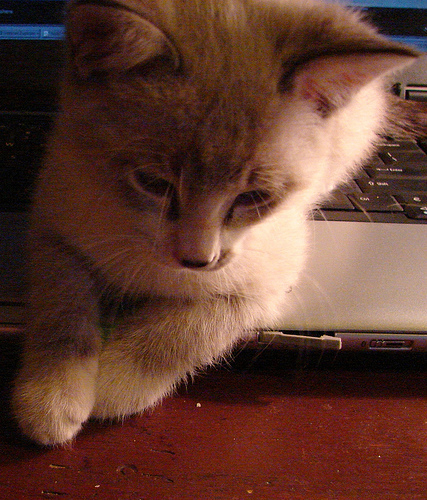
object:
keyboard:
[315, 117, 427, 221]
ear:
[279, 8, 419, 121]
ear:
[62, 1, 181, 84]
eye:
[231, 184, 274, 213]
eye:
[132, 166, 175, 205]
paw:
[12, 360, 95, 449]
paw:
[90, 344, 148, 417]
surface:
[320, 219, 427, 328]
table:
[0, 356, 427, 498]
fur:
[196, 36, 275, 140]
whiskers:
[250, 192, 263, 220]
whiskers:
[113, 159, 163, 184]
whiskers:
[237, 245, 337, 322]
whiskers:
[79, 231, 153, 249]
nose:
[175, 238, 218, 269]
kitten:
[8, 0, 421, 449]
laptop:
[0, 0, 427, 362]